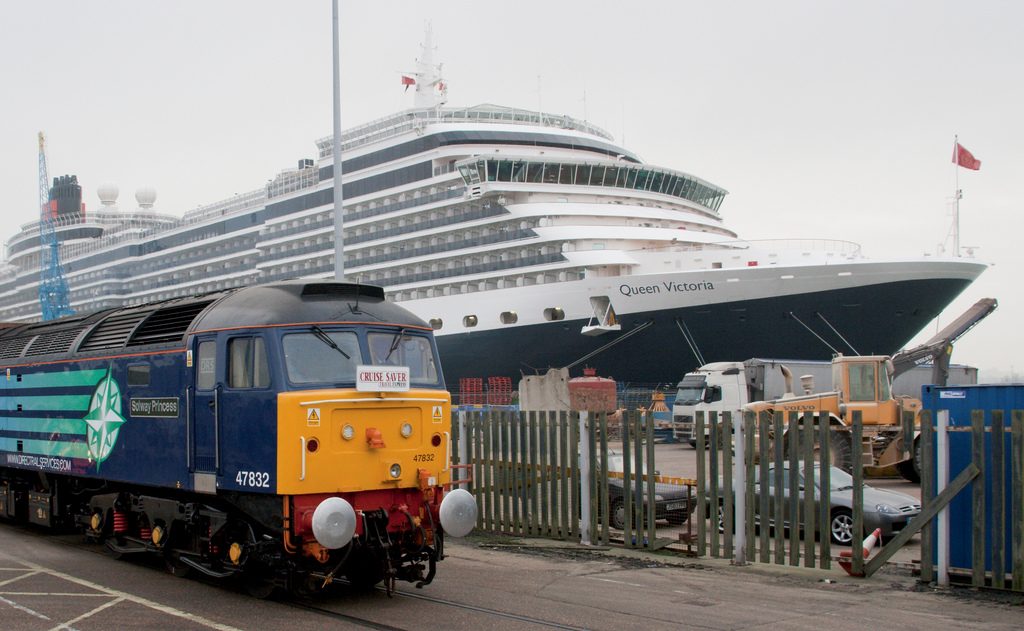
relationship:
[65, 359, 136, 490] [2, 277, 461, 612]
star on side of train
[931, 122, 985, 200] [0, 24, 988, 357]
flag on front of boat